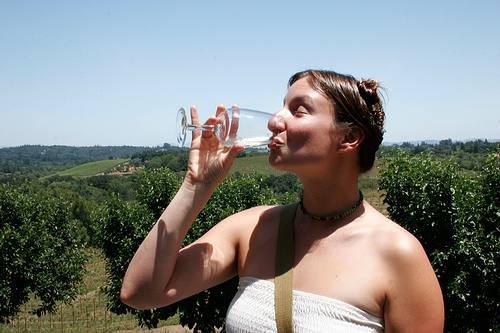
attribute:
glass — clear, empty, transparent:
[176, 109, 277, 153]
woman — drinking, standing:
[121, 69, 445, 333]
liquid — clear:
[222, 136, 274, 148]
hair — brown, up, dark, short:
[287, 68, 385, 174]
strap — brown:
[274, 204, 295, 332]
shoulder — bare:
[243, 200, 301, 241]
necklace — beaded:
[299, 189, 362, 222]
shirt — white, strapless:
[226, 275, 387, 333]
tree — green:
[3, 166, 499, 332]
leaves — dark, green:
[4, 153, 499, 332]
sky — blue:
[1, 2, 499, 148]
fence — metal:
[2, 300, 114, 331]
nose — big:
[269, 108, 286, 133]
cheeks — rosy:
[288, 119, 324, 154]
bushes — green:
[2, 153, 500, 332]